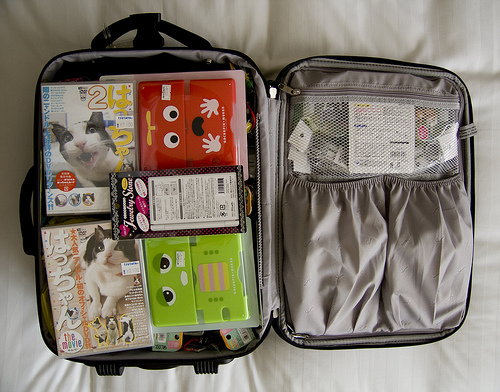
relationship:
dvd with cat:
[129, 76, 247, 157] [50, 108, 115, 179]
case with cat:
[40, 77, 246, 236] [75, 223, 140, 326]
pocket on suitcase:
[383, 173, 473, 333] [25, 10, 479, 375]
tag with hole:
[54, 168, 80, 188] [181, 328, 216, 349]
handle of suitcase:
[20, 158, 39, 258] [25, 10, 479, 375]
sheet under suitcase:
[302, 360, 415, 383] [25, 10, 479, 375]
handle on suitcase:
[18, 158, 39, 258] [25, 10, 479, 375]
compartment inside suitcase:
[284, 84, 466, 341] [25, 10, 479, 375]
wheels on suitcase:
[94, 358, 217, 381] [25, 10, 479, 375]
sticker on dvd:
[120, 262, 144, 277] [40, 217, 158, 357]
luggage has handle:
[19, 9, 482, 379] [84, 8, 229, 57]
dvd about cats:
[41, 76, 137, 217] [39, 59, 255, 355]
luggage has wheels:
[10, 4, 484, 382] [86, 348, 222, 382]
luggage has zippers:
[10, 4, 484, 382] [262, 75, 312, 104]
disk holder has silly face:
[137, 230, 255, 333] [152, 243, 237, 317]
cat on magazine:
[75, 223, 140, 326] [32, 215, 155, 365]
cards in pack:
[104, 164, 251, 240] [39, 54, 280, 364]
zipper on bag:
[285, 73, 325, 109] [61, 52, 494, 352]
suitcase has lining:
[25, 10, 479, 375] [282, 69, 464, 338]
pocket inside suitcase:
[275, 173, 388, 342] [25, 10, 479, 375]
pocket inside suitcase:
[383, 173, 473, 342] [25, 10, 479, 375]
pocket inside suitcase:
[383, 173, 473, 333] [25, 10, 479, 375]